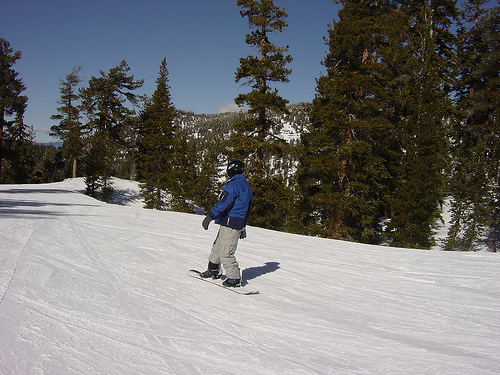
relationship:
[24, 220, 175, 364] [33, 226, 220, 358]
snow on ground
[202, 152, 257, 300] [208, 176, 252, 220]
person wearing jacket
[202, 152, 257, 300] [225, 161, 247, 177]
person wearing helmet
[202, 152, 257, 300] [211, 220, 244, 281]
person wearing pants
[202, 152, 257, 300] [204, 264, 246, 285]
person wearing boots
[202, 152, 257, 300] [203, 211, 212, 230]
person wearing gloves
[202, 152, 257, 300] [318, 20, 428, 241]
person by trees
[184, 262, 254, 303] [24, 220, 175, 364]
snowboard on snow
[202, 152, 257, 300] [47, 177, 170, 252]
person on slope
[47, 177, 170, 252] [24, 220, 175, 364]
slope has snow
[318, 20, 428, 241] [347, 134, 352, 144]
trees have bark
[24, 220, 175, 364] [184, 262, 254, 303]
snow on snowboard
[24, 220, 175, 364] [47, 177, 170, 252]
snow on slope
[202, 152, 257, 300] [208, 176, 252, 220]
person has jacket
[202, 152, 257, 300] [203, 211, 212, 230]
person has gloves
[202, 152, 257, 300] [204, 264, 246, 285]
person has boots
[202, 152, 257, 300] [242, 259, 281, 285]
person has shadow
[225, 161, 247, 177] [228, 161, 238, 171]
helmet has emblem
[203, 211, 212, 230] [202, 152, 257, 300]
gloves on person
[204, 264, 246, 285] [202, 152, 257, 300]
boots on person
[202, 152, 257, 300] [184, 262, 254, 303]
person on snowboard